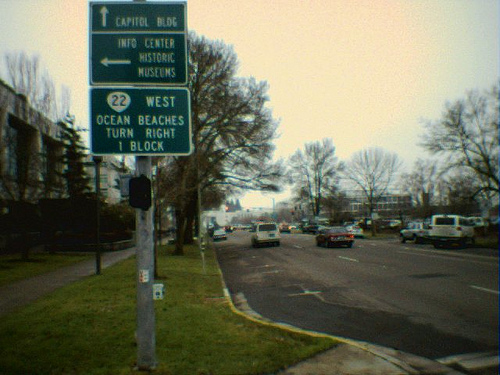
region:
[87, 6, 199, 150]
two green street signs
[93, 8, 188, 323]
green street sign on a metal pole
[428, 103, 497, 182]
trees without leaves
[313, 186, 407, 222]
big white building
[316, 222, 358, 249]
maroon driving down the road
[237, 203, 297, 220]
street light near cars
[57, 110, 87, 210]
pine trees with green needles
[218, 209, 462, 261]
many cars on the road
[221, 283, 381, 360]
yellow curb next to street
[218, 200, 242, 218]
red street light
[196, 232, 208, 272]
gray parking meter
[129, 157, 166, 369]
gray upright pole with 3 box attachments on it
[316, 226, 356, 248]
red car with one rear light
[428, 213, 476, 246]
parked white van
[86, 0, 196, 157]
green and white highway signs with writing and arrows on it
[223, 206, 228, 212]
red stop traffic light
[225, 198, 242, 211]
three pointy tree tops in the distance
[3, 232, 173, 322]
gray cement sidewalk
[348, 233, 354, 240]
single red tail light on a car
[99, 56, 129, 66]
white directional arrow on a green background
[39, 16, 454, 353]
this is an older photo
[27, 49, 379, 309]
the photo is slightly blurry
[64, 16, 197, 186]
these are informational signs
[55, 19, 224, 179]
these are street signs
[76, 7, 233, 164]
the signs are green and white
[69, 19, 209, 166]
the writing is white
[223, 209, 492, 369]
this is a city street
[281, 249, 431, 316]
the street is made of pavement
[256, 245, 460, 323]
the street lines are white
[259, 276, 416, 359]
the pavement is wet here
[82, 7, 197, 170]
the post has multiple signs on it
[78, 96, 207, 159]
to go to the beach, one has to go west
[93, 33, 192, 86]
the info center is also to the left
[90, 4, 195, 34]
the capitol building is straight ahead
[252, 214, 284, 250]
this vehicle is white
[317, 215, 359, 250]
this vehicle is dark red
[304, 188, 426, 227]
a multilevel building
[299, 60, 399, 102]
the sky is yellow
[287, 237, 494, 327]
a broken white line is painted on the street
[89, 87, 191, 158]
sign on the pole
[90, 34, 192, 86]
sign on the pole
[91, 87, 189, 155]
sign attached to the pole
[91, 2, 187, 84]
sign attached to the pole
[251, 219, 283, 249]
car driving down the street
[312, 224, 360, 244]
car driving down the street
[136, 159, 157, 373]
pole attached to the sign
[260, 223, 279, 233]
back windshield on the car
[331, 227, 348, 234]
back windshield to the car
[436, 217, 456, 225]
back windshield on the truck